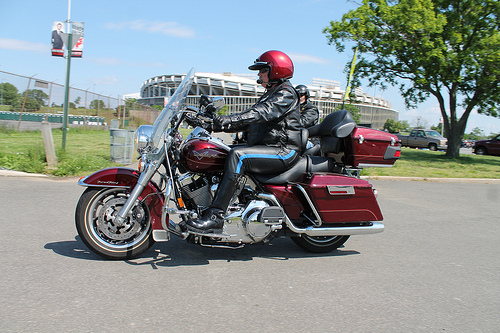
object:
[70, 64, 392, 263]
motorcycle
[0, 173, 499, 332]
road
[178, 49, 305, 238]
man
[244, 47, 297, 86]
helmet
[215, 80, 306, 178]
leather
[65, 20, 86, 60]
sign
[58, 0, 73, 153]
pole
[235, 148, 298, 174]
stripe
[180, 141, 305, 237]
pants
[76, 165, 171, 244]
fender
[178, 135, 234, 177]
gas tank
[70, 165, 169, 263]
wheel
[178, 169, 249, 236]
boot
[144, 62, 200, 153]
windshield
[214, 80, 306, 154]
jackets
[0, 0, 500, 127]
sky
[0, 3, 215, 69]
cloud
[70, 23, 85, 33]
lettering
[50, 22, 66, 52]
man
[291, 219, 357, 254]
tire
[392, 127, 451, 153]
truck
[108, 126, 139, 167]
can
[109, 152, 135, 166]
trash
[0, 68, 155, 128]
barbed-wire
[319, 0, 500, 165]
tree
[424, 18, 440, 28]
leaves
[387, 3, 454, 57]
branches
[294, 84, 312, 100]
helmet